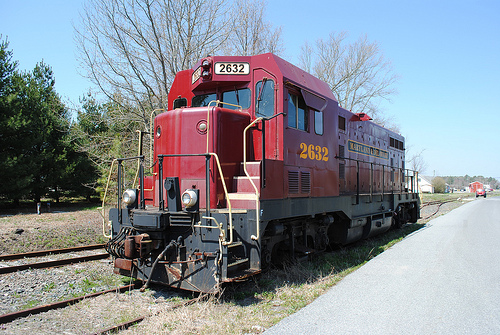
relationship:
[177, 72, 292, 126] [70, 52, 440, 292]
front windows of train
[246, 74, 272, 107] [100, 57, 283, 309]
window wiper on front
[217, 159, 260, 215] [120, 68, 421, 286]
stairs on front of train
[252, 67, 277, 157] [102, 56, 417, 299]
door to train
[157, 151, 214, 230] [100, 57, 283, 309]
railing on front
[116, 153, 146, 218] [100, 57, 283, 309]
railing on front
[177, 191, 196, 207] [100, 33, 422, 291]
light on front of train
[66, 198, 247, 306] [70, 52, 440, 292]
front bumper on train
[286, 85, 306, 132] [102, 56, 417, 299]
window on train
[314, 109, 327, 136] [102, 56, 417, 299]
window on train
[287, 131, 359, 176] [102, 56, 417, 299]
yellow numbers on train